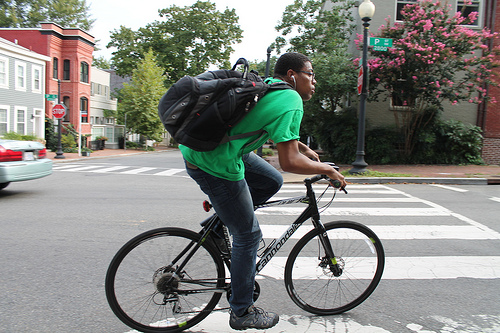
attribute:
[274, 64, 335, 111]
earbud — white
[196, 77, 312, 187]
shirt — green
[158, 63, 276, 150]
book bag — black, dark grey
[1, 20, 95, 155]
building — red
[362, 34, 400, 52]
sign — green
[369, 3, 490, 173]
tree — small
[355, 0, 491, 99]
blooms — pink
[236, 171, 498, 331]
crosswalk — white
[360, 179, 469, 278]
lines — white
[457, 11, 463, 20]
flower — pink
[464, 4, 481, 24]
flower — pink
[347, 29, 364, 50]
flower — pink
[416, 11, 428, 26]
flower — pink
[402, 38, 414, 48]
flower — pink